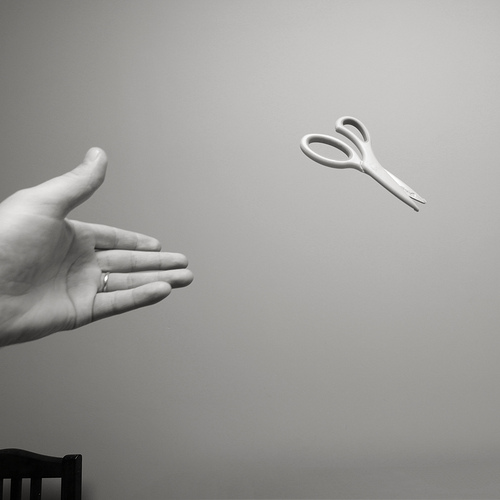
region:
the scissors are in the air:
[281, 109, 446, 219]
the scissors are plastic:
[266, 99, 441, 221]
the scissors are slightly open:
[399, 173, 429, 218]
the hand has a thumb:
[28, 139, 145, 197]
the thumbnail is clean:
[76, 141, 107, 163]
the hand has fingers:
[79, 210, 206, 335]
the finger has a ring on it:
[94, 266, 193, 288]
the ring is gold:
[95, 271, 115, 291]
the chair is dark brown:
[1, 433, 111, 495]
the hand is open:
[0, 144, 204, 356]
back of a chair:
[0, 445, 81, 499]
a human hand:
[3, 135, 224, 375]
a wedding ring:
[96, 268, 112, 298]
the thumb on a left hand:
[21, 134, 121, 224]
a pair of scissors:
[293, 106, 439, 220]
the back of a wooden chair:
[1, 443, 104, 498]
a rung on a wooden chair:
[23, 463, 46, 498]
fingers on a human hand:
[93, 217, 208, 334]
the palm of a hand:
[20, 220, 100, 317]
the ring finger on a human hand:
[91, 268, 210, 291]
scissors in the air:
[283, 108, 443, 225]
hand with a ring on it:
[6, 136, 195, 351]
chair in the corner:
[5, 430, 99, 499]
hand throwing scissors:
[4, 112, 463, 378]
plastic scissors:
[271, 123, 442, 228]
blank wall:
[217, 251, 469, 498]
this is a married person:
[84, 265, 218, 313]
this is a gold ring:
[90, 270, 121, 300]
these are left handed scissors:
[280, 140, 435, 230]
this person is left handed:
[11, 156, 201, 368]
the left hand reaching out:
[0, 142, 193, 350]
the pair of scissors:
[299, 114, 425, 214]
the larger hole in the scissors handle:
[297, 127, 357, 172]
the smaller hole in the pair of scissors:
[333, 108, 373, 148]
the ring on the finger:
[98, 272, 113, 293]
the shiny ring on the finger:
[97, 267, 111, 292]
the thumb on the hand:
[35, 139, 108, 220]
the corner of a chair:
[3, 442, 83, 497]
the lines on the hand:
[35, 242, 87, 314]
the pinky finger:
[98, 280, 171, 317]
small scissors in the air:
[283, 113, 426, 223]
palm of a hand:
[1, 197, 178, 325]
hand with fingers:
[24, 156, 193, 323]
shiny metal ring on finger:
[85, 259, 125, 301]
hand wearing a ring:
[13, 161, 207, 315]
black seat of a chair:
[1, 455, 86, 497]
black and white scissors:
[280, 87, 441, 229]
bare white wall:
[150, 63, 266, 217]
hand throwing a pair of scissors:
[5, 100, 441, 386]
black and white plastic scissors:
[309, 112, 374, 179]